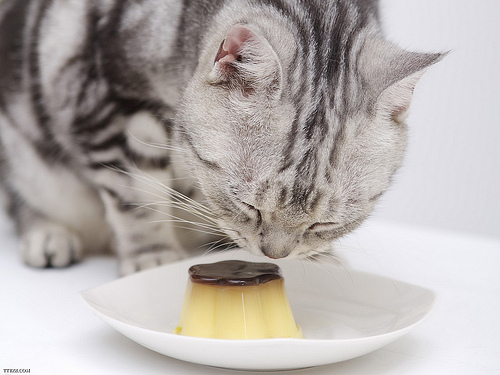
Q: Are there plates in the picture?
A: Yes, there is a plate.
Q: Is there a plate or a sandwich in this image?
A: Yes, there is a plate.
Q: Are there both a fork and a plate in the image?
A: No, there is a plate but no forks.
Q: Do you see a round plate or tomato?
A: Yes, there is a round plate.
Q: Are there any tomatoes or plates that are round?
A: Yes, the plate is round.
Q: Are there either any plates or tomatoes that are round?
A: Yes, the plate is round.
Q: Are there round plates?
A: Yes, there is a round plate.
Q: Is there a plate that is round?
A: Yes, there is a plate that is round.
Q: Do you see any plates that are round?
A: Yes, there is a plate that is round.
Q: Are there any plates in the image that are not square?
A: Yes, there is a round plate.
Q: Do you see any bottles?
A: No, there are no bottles.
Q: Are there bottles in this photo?
A: No, there are no bottles.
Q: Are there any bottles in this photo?
A: No, there are no bottles.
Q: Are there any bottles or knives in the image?
A: No, there are no bottles or knives.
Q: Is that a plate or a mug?
A: That is a plate.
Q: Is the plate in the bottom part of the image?
A: Yes, the plate is in the bottom of the image.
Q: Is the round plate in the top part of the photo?
A: No, the plate is in the bottom of the image.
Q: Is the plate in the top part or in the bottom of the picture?
A: The plate is in the bottom of the image.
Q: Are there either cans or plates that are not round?
A: No, there is a plate but it is round.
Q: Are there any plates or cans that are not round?
A: No, there is a plate but it is round.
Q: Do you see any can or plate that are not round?
A: No, there is a plate but it is round.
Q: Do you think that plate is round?
A: Yes, the plate is round.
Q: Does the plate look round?
A: Yes, the plate is round.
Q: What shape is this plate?
A: The plate is round.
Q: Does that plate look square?
A: No, the plate is round.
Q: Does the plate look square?
A: No, the plate is round.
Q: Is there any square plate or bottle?
A: No, there is a plate but it is round.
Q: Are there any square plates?
A: No, there is a plate but it is round.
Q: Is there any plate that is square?
A: No, there is a plate but it is round.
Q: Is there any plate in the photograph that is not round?
A: No, there is a plate but it is round.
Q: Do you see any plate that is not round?
A: No, there is a plate but it is round.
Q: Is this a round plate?
A: Yes, this is a round plate.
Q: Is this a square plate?
A: No, this is a round plate.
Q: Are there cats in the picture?
A: Yes, there is a cat.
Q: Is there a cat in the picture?
A: Yes, there is a cat.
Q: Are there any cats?
A: Yes, there is a cat.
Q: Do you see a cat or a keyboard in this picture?
A: Yes, there is a cat.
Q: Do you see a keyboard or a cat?
A: Yes, there is a cat.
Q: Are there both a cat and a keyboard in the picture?
A: No, there is a cat but no keyboards.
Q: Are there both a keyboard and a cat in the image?
A: No, there is a cat but no keyboards.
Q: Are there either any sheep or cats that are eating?
A: Yes, the cat is eating.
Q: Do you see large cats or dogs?
A: Yes, there is a large cat.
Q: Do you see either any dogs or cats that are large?
A: Yes, the cat is large.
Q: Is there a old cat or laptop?
A: Yes, there is an old cat.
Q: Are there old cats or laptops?
A: Yes, there is an old cat.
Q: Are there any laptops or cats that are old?
A: Yes, the cat is old.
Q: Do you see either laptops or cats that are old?
A: Yes, the cat is old.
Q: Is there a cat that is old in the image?
A: Yes, there is an old cat.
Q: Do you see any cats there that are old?
A: Yes, there is a cat that is old.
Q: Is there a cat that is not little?
A: Yes, there is a old cat.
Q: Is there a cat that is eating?
A: Yes, there is a cat that is eating.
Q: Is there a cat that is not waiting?
A: Yes, there is a cat that is eating.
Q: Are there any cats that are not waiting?
A: Yes, there is a cat that is eating.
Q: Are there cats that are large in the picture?
A: Yes, there is a large cat.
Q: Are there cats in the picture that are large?
A: Yes, there is a cat that is large.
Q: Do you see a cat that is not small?
A: Yes, there is a large cat.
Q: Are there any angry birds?
A: No, there are no angry birds.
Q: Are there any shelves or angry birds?
A: No, there are no angry birds or shelves.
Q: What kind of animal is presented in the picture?
A: The animal is a cat.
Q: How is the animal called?
A: The animal is a cat.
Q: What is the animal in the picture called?
A: The animal is a cat.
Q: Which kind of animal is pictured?
A: The animal is a cat.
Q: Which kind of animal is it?
A: The animal is a cat.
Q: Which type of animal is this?
A: This is a cat.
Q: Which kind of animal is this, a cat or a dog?
A: This is a cat.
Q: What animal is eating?
A: The animal is a cat.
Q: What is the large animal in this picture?
A: The animal is a cat.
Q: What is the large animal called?
A: The animal is a cat.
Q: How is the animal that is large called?
A: The animal is a cat.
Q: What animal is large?
A: The animal is a cat.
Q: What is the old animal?
A: The animal is a cat.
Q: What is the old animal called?
A: The animal is a cat.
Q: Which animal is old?
A: The animal is a cat.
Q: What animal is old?
A: The animal is a cat.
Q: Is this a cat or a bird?
A: This is a cat.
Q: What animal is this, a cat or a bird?
A: This is a cat.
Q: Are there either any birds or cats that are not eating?
A: No, there is a cat but it is eating.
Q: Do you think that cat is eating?
A: Yes, the cat is eating.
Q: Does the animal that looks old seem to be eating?
A: Yes, the cat is eating.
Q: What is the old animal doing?
A: The cat is eating.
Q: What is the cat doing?
A: The cat is eating.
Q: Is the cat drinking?
A: No, the cat is eating.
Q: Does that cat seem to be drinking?
A: No, the cat is eating.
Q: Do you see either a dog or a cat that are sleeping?
A: No, there is a cat but it is eating.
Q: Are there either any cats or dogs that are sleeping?
A: No, there is a cat but it is eating.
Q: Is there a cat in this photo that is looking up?
A: No, there is a cat but it is eating.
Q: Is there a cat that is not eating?
A: No, there is a cat but it is eating.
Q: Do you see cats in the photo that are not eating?
A: No, there is a cat but it is eating.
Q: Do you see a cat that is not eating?
A: No, there is a cat but it is eating.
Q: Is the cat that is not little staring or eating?
A: The cat is eating.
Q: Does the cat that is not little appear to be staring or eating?
A: The cat is eating.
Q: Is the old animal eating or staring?
A: The cat is eating.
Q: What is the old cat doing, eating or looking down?
A: The cat is eating.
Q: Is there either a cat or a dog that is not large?
A: No, there is a cat but it is large.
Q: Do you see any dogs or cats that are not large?
A: No, there is a cat but it is large.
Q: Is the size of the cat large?
A: Yes, the cat is large.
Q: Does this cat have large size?
A: Yes, the cat is large.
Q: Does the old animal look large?
A: Yes, the cat is large.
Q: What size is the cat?
A: The cat is large.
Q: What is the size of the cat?
A: The cat is large.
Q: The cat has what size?
A: The cat is large.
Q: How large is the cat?
A: The cat is large.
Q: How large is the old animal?
A: The cat is large.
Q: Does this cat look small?
A: No, the cat is large.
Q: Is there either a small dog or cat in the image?
A: No, there is a cat but it is large.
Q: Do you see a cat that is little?
A: No, there is a cat but it is large.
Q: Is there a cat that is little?
A: No, there is a cat but it is large.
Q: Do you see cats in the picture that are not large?
A: No, there is a cat but it is large.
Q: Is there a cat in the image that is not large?
A: No, there is a cat but it is large.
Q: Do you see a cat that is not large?
A: No, there is a cat but it is large.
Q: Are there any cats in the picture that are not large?
A: No, there is a cat but it is large.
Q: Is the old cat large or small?
A: The cat is large.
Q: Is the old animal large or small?
A: The cat is large.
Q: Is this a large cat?
A: Yes, this is a large cat.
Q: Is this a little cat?
A: No, this is a large cat.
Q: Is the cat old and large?
A: Yes, the cat is old and large.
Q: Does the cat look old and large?
A: Yes, the cat is old and large.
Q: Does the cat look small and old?
A: No, the cat is old but large.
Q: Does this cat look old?
A: Yes, the cat is old.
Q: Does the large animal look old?
A: Yes, the cat is old.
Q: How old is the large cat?
A: The cat is old.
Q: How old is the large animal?
A: The cat is old.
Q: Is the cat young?
A: No, the cat is old.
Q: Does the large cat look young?
A: No, the cat is old.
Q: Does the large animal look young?
A: No, the cat is old.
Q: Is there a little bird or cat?
A: No, there is a cat but it is old.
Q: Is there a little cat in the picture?
A: No, there is a cat but it is old.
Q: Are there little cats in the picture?
A: No, there is a cat but it is old.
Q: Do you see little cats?
A: No, there is a cat but it is old.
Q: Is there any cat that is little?
A: No, there is a cat but it is old.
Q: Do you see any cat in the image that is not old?
A: No, there is a cat but it is old.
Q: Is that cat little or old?
A: The cat is old.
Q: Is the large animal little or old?
A: The cat is old.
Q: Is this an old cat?
A: Yes, this is an old cat.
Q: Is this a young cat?
A: No, this is an old cat.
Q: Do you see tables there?
A: Yes, there is a table.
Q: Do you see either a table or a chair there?
A: Yes, there is a table.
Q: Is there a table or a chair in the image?
A: Yes, there is a table.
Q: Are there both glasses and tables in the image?
A: No, there is a table but no glasses.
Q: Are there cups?
A: No, there are no cups.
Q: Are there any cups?
A: No, there are no cups.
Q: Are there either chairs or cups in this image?
A: No, there are no cups or chairs.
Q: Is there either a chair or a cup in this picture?
A: No, there are no cups or chairs.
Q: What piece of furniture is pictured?
A: The piece of furniture is a table.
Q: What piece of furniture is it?
A: The piece of furniture is a table.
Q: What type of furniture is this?
A: This is a table.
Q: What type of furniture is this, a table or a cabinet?
A: This is a table.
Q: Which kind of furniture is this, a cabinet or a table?
A: This is a table.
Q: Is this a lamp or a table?
A: This is a table.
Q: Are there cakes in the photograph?
A: Yes, there is a cake.